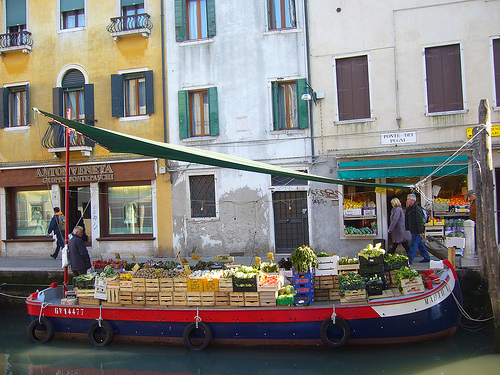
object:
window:
[108, 208, 127, 218]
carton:
[186, 269, 203, 292]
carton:
[230, 266, 258, 291]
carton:
[311, 253, 339, 277]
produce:
[276, 285, 297, 298]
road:
[0, 255, 499, 273]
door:
[270, 190, 310, 255]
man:
[46, 206, 66, 260]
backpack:
[58, 214, 67, 230]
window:
[190, 90, 202, 135]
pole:
[468, 97, 499, 328]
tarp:
[33, 105, 414, 188]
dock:
[407, 251, 499, 269]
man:
[402, 192, 431, 264]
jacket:
[402, 204, 427, 235]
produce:
[395, 265, 420, 282]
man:
[64, 225, 93, 279]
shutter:
[111, 73, 126, 118]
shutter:
[145, 70, 153, 113]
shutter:
[20, 89, 28, 126]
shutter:
[0, 84, 8, 129]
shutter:
[83, 82, 93, 126]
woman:
[384, 195, 411, 265]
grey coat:
[385, 205, 410, 243]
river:
[0, 309, 497, 374]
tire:
[316, 315, 351, 348]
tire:
[87, 317, 113, 347]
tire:
[26, 318, 57, 343]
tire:
[180, 319, 213, 353]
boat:
[24, 244, 464, 352]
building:
[0, 0, 175, 258]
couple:
[386, 192, 431, 264]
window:
[294, 78, 312, 129]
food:
[106, 257, 115, 263]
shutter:
[270, 0, 286, 30]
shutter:
[187, 0, 198, 42]